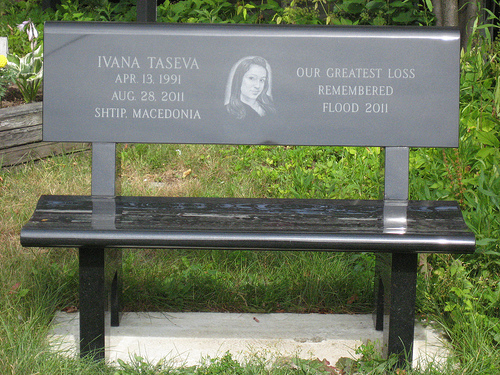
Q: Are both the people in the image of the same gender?
A: Yes, all the people are female.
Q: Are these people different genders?
A: No, all the people are female.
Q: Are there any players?
A: No, there are no players.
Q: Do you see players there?
A: No, there are no players.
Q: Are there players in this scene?
A: No, there are no players.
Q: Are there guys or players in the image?
A: No, there are no players or guys.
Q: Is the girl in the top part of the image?
A: Yes, the girl is in the top of the image.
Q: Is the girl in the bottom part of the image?
A: No, the girl is in the top of the image.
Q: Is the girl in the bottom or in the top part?
A: The girl is in the top of the image.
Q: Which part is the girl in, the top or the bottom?
A: The girl is in the top of the image.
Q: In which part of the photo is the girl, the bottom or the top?
A: The girl is in the top of the image.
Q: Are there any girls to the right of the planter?
A: Yes, there is a girl to the right of the planter.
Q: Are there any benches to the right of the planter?
A: No, there is a girl to the right of the planter.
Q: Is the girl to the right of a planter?
A: Yes, the girl is to the right of a planter.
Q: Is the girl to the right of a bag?
A: No, the girl is to the right of a planter.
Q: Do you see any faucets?
A: No, there are no faucets.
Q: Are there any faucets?
A: No, there are no faucets.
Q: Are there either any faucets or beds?
A: No, there are no faucets or beds.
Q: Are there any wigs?
A: No, there are no wigs.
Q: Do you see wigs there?
A: No, there are no wigs.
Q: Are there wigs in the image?
A: No, there are no wigs.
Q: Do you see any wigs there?
A: No, there are no wigs.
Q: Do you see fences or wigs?
A: No, there are no wigs or fences.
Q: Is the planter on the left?
A: Yes, the planter is on the left of the image.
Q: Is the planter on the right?
A: No, the planter is on the left of the image.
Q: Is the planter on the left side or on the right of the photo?
A: The planter is on the left of the image.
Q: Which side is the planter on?
A: The planter is on the left of the image.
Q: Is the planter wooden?
A: Yes, the planter is wooden.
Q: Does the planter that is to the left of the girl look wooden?
A: Yes, the planter is wooden.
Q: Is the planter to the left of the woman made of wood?
A: Yes, the planter is made of wood.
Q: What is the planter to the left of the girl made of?
A: The planter is made of wood.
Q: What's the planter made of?
A: The planter is made of wood.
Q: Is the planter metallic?
A: No, the planter is wooden.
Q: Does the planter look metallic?
A: No, the planter is wooden.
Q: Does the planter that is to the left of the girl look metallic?
A: No, the planter is wooden.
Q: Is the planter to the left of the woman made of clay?
A: No, the planter is made of wood.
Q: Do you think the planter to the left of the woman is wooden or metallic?
A: The planter is wooden.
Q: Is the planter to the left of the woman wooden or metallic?
A: The planter is wooden.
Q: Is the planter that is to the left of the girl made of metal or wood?
A: The planter is made of wood.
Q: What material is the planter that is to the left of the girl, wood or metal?
A: The planter is made of wood.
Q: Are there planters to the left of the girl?
A: Yes, there is a planter to the left of the girl.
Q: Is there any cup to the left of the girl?
A: No, there is a planter to the left of the girl.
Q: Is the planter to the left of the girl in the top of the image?
A: Yes, the planter is to the left of the girl.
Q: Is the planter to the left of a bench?
A: No, the planter is to the left of the girl.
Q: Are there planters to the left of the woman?
A: Yes, there is a planter to the left of the woman.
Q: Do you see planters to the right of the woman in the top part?
A: No, the planter is to the left of the woman.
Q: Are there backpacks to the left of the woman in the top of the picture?
A: No, there is a planter to the left of the woman.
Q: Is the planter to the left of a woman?
A: Yes, the planter is to the left of a woman.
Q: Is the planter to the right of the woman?
A: No, the planter is to the left of the woman.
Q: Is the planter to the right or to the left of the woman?
A: The planter is to the left of the woman.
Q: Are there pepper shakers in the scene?
A: No, there are no pepper shakers.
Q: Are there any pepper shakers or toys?
A: No, there are no pepper shakers or toys.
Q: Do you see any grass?
A: Yes, there is grass.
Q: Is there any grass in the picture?
A: Yes, there is grass.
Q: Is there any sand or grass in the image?
A: Yes, there is grass.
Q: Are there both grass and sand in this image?
A: No, there is grass but no sand.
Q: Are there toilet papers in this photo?
A: No, there are no toilet papers.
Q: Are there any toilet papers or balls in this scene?
A: No, there are no toilet papers or balls.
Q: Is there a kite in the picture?
A: No, there are no kites.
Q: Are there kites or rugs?
A: No, there are no kites or rugs.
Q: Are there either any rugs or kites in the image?
A: No, there are no kites or rugs.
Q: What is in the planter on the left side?
A: The plants are in the planter.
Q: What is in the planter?
A: The plants are in the planter.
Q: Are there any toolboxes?
A: No, there are no toolboxes.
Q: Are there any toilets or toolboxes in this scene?
A: No, there are no toolboxes or toilets.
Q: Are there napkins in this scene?
A: No, there are no napkins.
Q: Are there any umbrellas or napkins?
A: No, there are no napkins or umbrellas.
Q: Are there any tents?
A: No, there are no tents.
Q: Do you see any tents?
A: No, there are no tents.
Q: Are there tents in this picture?
A: No, there are no tents.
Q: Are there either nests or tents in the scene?
A: No, there are no tents or nests.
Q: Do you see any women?
A: Yes, there is a woman.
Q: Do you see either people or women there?
A: Yes, there is a woman.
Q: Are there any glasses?
A: No, there are no glasses.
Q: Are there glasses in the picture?
A: No, there are no glasses.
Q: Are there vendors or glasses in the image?
A: No, there are no glasses or vendors.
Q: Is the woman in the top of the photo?
A: Yes, the woman is in the top of the image.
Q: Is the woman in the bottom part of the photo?
A: No, the woman is in the top of the image.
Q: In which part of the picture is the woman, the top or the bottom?
A: The woman is in the top of the image.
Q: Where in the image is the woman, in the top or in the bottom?
A: The woman is in the top of the image.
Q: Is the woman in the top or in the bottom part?
A: The woman is in the top of the image.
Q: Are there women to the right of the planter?
A: Yes, there is a woman to the right of the planter.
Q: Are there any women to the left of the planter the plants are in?
A: No, the woman is to the right of the planter.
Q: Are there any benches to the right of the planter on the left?
A: No, there is a woman to the right of the planter.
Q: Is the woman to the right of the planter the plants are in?
A: Yes, the woman is to the right of the planter.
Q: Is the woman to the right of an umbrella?
A: No, the woman is to the right of the planter.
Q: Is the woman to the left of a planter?
A: No, the woman is to the right of a planter.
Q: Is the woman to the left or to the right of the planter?
A: The woman is to the right of the planter.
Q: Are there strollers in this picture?
A: No, there are no strollers.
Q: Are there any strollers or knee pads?
A: No, there are no strollers or knee pads.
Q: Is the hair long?
A: Yes, the hair is long.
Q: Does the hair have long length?
A: Yes, the hair is long.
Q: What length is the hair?
A: The hair is long.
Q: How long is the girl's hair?
A: The hair is long.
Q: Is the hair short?
A: No, the hair is long.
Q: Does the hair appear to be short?
A: No, the hair is long.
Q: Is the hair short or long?
A: The hair is long.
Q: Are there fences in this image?
A: No, there are no fences.